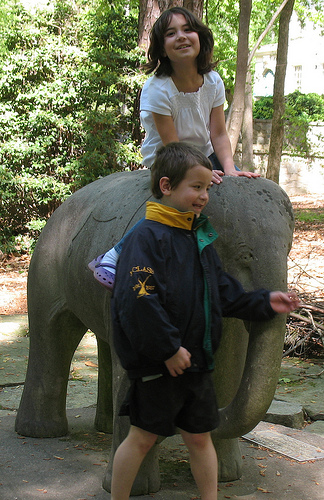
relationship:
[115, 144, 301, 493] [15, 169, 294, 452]
child near elephant statue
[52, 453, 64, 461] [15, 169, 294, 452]
leaf near elephant statue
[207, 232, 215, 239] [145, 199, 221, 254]
button on collar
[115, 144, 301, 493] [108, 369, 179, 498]
child has leg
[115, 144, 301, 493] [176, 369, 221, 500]
child has leg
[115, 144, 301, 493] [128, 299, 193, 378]
child has hand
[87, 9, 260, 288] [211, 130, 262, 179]
girl has hand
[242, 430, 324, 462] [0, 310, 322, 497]
plaque on ground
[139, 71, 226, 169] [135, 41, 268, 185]
shirt on girl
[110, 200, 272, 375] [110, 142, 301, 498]
jacket on child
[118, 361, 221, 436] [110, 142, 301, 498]
shorts on child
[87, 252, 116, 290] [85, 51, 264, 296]
shoe on girl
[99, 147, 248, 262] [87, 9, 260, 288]
pants on girl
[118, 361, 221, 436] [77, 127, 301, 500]
shorts on boy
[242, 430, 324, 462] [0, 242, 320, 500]
plaque on ground